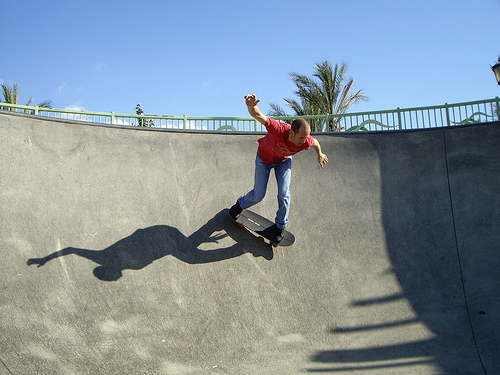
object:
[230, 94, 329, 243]
skater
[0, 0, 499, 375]
skate park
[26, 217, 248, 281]
shadow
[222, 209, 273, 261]
shadow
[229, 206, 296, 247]
skate board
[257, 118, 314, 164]
t-shirt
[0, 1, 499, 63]
sky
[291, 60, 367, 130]
plant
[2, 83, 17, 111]
plant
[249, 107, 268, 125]
arm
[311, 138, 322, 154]
arm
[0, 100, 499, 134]
fence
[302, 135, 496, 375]
shadow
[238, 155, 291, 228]
jeans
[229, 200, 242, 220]
shoe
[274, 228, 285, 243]
shoe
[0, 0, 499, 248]
background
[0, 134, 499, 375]
ramp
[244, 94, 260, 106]
hand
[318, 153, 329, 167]
hand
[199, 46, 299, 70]
air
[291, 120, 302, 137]
hair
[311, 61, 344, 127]
frond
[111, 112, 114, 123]
post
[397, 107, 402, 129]
post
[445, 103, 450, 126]
post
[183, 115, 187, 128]
post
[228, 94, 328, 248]
stunt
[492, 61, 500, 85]
street light